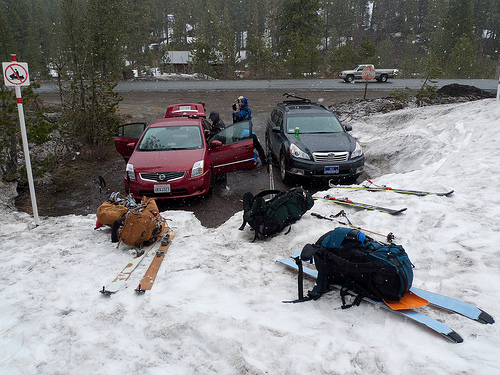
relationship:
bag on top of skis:
[288, 223, 421, 316] [273, 219, 498, 343]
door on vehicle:
[207, 119, 256, 176] [114, 95, 255, 207]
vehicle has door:
[114, 95, 255, 207] [112, 121, 145, 156]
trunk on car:
[166, 102, 205, 117] [114, 95, 255, 207]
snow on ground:
[412, 52, 420, 60] [19, 226, 55, 250]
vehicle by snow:
[265, 92, 366, 191] [361, 121, 380, 144]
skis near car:
[318, 174, 457, 215] [265, 92, 366, 191]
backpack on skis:
[288, 223, 421, 316] [273, 219, 498, 343]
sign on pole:
[1, 61, 31, 88] [14, 89, 55, 229]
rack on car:
[270, 88, 322, 104] [265, 92, 366, 191]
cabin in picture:
[149, 46, 203, 76] [160, 50, 226, 73]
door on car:
[207, 119, 256, 176] [114, 95, 255, 207]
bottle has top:
[289, 122, 301, 141] [296, 126, 302, 131]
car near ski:
[265, 92, 366, 191] [318, 174, 457, 215]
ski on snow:
[318, 174, 457, 215] [388, 196, 408, 206]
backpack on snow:
[236, 181, 312, 244] [241, 242, 266, 265]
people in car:
[200, 106, 235, 142] [114, 95, 255, 207]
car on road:
[338, 60, 400, 84] [352, 82, 392, 90]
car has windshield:
[265, 92, 366, 191] [285, 110, 344, 133]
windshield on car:
[139, 124, 203, 153] [114, 95, 255, 207]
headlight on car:
[186, 160, 208, 179] [114, 95, 255, 207]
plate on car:
[149, 185, 172, 193] [114, 95, 255, 207]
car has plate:
[265, 92, 366, 191] [325, 164, 340, 174]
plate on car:
[325, 164, 340, 174] [265, 92, 366, 191]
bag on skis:
[288, 223, 421, 316] [273, 219, 498, 343]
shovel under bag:
[380, 288, 429, 313] [288, 223, 421, 316]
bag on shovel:
[288, 223, 421, 316] [380, 288, 429, 313]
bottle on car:
[289, 122, 301, 141] [265, 92, 366, 191]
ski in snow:
[318, 174, 457, 215] [418, 167, 447, 187]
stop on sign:
[363, 70, 374, 79] [361, 66, 376, 81]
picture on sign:
[6, 64, 29, 84] [1, 61, 31, 88]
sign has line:
[1, 61, 31, 88] [11, 65, 21, 81]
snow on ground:
[418, 167, 447, 187] [19, 226, 55, 250]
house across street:
[160, 50, 226, 73] [152, 81, 227, 92]